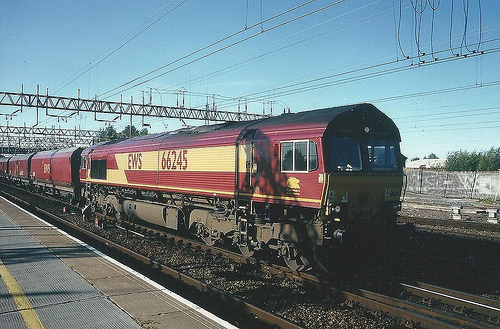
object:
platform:
[1, 195, 225, 329]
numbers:
[161, 150, 189, 171]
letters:
[128, 153, 133, 169]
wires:
[413, 121, 500, 133]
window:
[280, 141, 293, 171]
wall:
[400, 167, 499, 202]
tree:
[476, 142, 499, 173]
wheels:
[280, 244, 311, 272]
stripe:
[78, 176, 323, 205]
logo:
[127, 151, 144, 170]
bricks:
[0, 229, 25, 245]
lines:
[59, 41, 137, 84]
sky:
[1, 3, 500, 139]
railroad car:
[1, 104, 413, 275]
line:
[0, 264, 44, 329]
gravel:
[297, 303, 382, 323]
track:
[354, 281, 495, 329]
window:
[325, 138, 362, 172]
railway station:
[4, 170, 500, 329]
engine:
[70, 103, 411, 279]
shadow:
[357, 227, 500, 296]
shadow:
[0, 239, 106, 264]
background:
[0, 2, 498, 169]